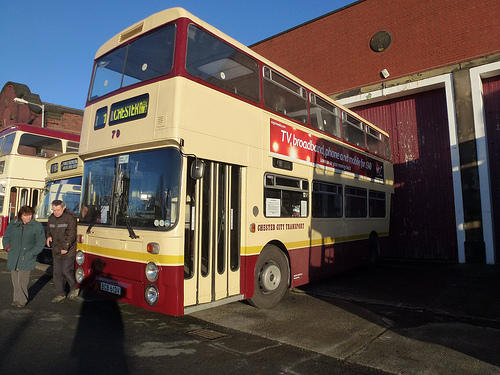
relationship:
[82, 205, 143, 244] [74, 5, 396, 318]
windshield wipers are on bus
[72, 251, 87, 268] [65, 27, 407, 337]
light in bus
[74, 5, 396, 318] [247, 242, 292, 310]
bus has wheel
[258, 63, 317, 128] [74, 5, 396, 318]
window on bus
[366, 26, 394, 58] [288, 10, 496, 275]
circle on building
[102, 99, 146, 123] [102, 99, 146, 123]
display on display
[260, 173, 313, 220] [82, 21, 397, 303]
window of bus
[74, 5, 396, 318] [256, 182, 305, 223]
bus has window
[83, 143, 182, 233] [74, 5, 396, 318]
window of bus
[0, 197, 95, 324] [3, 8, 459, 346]
people by buses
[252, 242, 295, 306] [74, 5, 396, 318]
wheel of bus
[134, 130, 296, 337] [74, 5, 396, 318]
doors of bus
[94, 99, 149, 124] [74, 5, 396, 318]
display on top of bus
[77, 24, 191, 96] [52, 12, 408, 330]
windshield in front of bus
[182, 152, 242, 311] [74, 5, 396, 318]
doors in bus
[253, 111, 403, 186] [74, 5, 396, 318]
sign in bus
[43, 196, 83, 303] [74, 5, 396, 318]
man next to bus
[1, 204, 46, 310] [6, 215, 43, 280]
people wearing a coat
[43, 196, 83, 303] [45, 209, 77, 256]
man wearing a coat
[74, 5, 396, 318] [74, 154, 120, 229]
bus has window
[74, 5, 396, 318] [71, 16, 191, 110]
bus has windshield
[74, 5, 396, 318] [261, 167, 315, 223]
bus has window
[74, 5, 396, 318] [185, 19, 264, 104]
bus has window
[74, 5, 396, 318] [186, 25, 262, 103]
bus has window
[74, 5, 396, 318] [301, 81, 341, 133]
bus has window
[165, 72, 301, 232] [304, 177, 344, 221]
bus has window